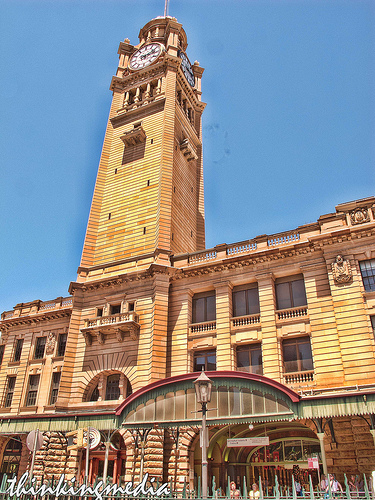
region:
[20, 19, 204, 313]
large clock tower in front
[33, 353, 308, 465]
archway on building front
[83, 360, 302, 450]
red archway on building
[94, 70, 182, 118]
small columns on front of tower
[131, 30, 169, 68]
large clock on front of tower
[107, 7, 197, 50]
roof over clock tower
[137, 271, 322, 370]
windows on front of builiding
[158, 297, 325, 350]
balcony design on front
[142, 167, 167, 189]
small window slits on tower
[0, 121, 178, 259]
brown and yellow colored clock tower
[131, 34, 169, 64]
clock on the tower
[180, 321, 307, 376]
windows on the building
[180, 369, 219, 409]
light pole outside somewhere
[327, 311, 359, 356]
yellow building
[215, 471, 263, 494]
people standing outside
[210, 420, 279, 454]
sign above the land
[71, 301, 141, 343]
balcony next to window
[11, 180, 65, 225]
blue sky in the background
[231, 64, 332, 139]
sky with no clouds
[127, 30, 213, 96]
two clocks on the building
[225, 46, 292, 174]
the sky is clear and visible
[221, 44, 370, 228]
the sky is clear and visible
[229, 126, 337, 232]
the sky is clear and visible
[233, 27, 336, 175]
the sky is clear and visible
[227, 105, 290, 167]
the sky is clear and visible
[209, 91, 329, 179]
the sky is clear and visible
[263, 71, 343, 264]
the sky is clear and visible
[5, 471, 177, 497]
signature of thinkmedia company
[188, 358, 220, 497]
tall street light on sidewalk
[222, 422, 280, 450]
hanging sign in entryway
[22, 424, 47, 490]
back of sign on street or sidewalk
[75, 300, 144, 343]
upstairs balcony with rails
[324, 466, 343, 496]
person wearing white shirt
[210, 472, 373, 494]
green patina iron fence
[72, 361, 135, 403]
arch shaped window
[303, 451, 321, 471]
red and white sign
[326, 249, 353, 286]
decorative architecture on building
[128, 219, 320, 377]
the windows are close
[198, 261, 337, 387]
the windows are close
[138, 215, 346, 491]
the windows are close